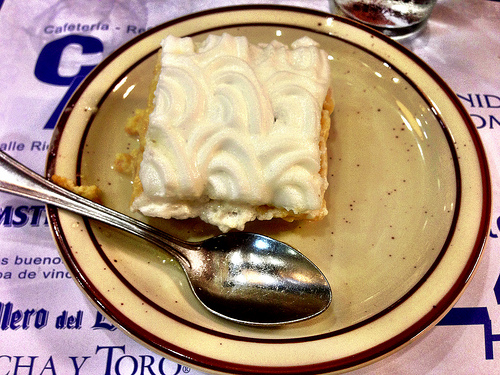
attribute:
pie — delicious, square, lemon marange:
[132, 34, 337, 233]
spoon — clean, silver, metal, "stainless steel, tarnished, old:
[1, 149, 334, 328]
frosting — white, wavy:
[144, 34, 327, 201]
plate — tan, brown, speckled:
[43, 5, 489, 373]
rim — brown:
[476, 112, 494, 283]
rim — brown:
[57, 220, 85, 296]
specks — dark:
[376, 102, 419, 162]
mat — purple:
[3, 3, 498, 374]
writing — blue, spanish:
[3, 299, 89, 375]